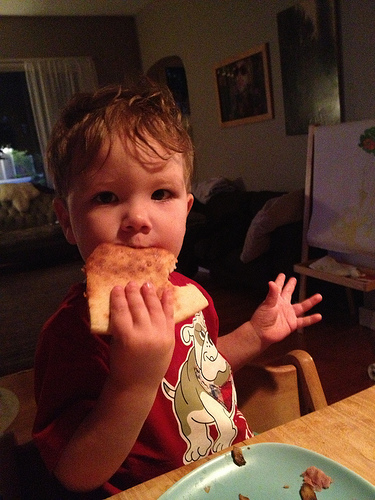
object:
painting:
[276, 1, 341, 136]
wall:
[172, 0, 227, 46]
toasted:
[82, 242, 209, 334]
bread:
[80, 243, 208, 334]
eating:
[46, 79, 210, 331]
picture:
[214, 51, 268, 122]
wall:
[230, 14, 269, 49]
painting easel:
[305, 119, 375, 254]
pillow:
[240, 192, 301, 262]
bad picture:
[277, 0, 343, 135]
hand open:
[249, 272, 322, 347]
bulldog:
[162, 309, 237, 467]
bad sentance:
[291, 42, 343, 120]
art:
[215, 51, 268, 122]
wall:
[231, 20, 256, 39]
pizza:
[79, 243, 208, 337]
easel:
[294, 121, 375, 335]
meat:
[298, 465, 333, 488]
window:
[1, 70, 47, 183]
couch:
[0, 181, 56, 379]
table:
[307, 122, 375, 255]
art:
[306, 119, 374, 256]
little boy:
[30, 76, 322, 494]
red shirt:
[31, 270, 258, 495]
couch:
[183, 175, 307, 297]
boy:
[29, 80, 323, 494]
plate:
[152, 437, 373, 499]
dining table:
[101, 384, 375, 498]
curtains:
[23, 56, 99, 190]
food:
[83, 245, 208, 335]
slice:
[81, 240, 210, 333]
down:
[87, 282, 210, 334]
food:
[187, 445, 332, 497]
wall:
[250, 151, 282, 179]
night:
[0, 78, 24, 131]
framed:
[212, 44, 272, 128]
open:
[258, 309, 300, 368]